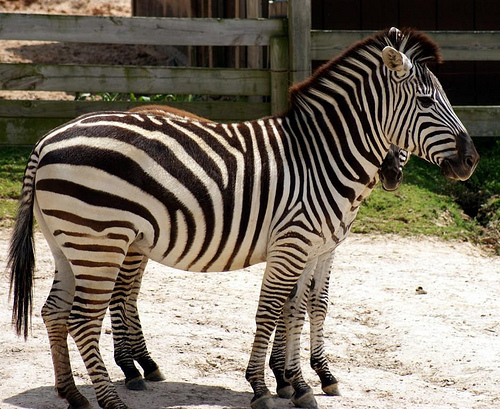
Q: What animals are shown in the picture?
A: Zebras.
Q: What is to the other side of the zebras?
A: Wooden fence.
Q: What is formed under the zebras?
A: Shadow.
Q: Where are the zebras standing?
A: In a dirt field.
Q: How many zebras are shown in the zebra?
A: 2.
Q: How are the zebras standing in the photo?
A: Side by side.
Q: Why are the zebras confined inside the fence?
A: Visitors safety.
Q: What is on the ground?
A: Grey dirt.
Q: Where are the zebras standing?
A: Bare ground.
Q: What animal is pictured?
A: Zebra.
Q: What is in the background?
A: Building.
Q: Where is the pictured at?
A: Zoo.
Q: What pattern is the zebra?
A: Striped.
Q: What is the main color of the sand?
A: White.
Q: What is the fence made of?
A: Wood.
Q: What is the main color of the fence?
A: Gray.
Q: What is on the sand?
A: Zebras.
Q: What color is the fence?
A: Brown.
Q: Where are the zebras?
A: On the sand.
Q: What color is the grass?
A: Green.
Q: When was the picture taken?
A: Daytime.